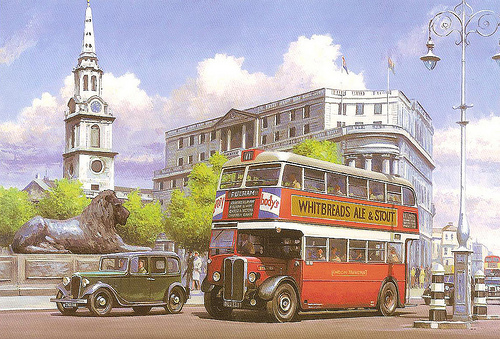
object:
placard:
[286, 195, 407, 228]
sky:
[0, 0, 500, 194]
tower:
[69, 9, 112, 196]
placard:
[226, 193, 260, 219]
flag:
[340, 56, 347, 71]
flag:
[382, 53, 397, 73]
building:
[154, 88, 436, 285]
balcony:
[164, 88, 434, 140]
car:
[46, 244, 190, 318]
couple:
[182, 250, 202, 292]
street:
[2, 298, 498, 336]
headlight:
[248, 270, 256, 280]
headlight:
[209, 269, 223, 281]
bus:
[193, 143, 430, 325]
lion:
[3, 187, 136, 260]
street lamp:
[420, 1, 498, 321]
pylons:
[423, 257, 450, 324]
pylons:
[468, 262, 488, 322]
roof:
[103, 249, 172, 258]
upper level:
[208, 149, 426, 235]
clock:
[89, 98, 103, 114]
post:
[450, 2, 485, 323]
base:
[451, 245, 477, 321]